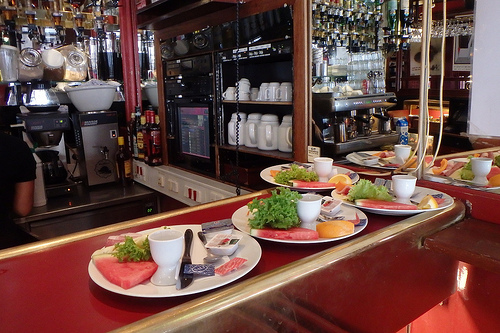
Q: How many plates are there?
A: Five.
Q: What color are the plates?
A: White.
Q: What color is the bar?
A: Red.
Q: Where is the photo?
A: Bar.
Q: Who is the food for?
A: Patron.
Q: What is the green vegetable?
A: Lettuce.